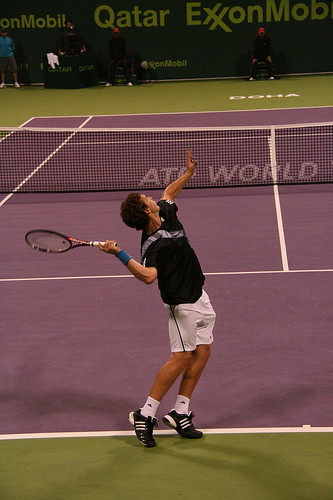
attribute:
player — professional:
[101, 149, 218, 449]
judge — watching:
[245, 24, 278, 83]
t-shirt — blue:
[1, 36, 20, 58]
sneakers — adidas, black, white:
[125, 408, 204, 448]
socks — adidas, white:
[138, 395, 194, 418]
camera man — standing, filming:
[54, 19, 88, 55]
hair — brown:
[118, 192, 151, 234]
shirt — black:
[138, 199, 207, 305]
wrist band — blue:
[114, 250, 134, 268]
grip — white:
[88, 239, 118, 249]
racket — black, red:
[22, 228, 121, 254]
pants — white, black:
[162, 285, 218, 353]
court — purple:
[1, 102, 332, 440]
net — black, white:
[1, 120, 333, 193]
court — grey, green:
[2, 72, 333, 499]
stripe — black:
[169, 304, 189, 353]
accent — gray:
[140, 227, 186, 256]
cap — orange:
[256, 27, 266, 35]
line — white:
[1, 424, 333, 443]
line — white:
[14, 104, 332, 127]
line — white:
[206, 131, 332, 275]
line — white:
[1, 134, 129, 282]